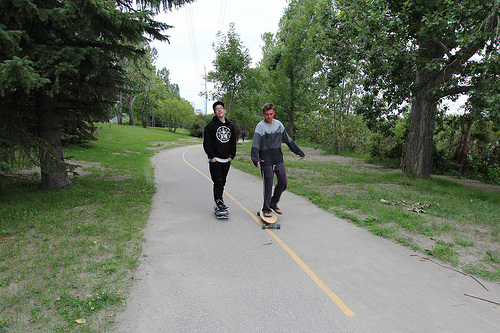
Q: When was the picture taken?
A: Daytime.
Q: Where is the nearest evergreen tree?
A: To the left of the men.